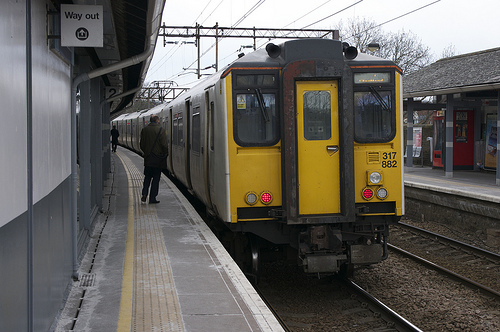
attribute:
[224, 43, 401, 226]
back — yellow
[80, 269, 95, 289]
metal grating — small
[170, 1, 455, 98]
power lines — overhead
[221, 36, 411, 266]
train — back 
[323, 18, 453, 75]
trees — bare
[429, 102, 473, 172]
vending machine — red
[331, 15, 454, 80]
trees — leafless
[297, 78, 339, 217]
metal door — yellow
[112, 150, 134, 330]
line — yellow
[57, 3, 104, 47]
sign — white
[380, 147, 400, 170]
numbers — black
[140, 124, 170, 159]
coat — olive colored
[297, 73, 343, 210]
door — yellow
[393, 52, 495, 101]
roof — gray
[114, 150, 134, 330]
stripe — yellow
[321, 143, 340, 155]
latch — silver 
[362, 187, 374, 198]
light — red, rear, lit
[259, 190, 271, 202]
light — red, rear, lit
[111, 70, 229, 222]
side — silver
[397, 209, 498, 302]
tracks — brown, metal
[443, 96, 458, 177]
support — gray